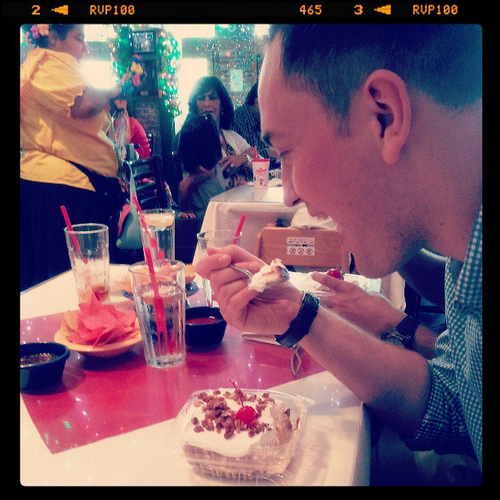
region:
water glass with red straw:
[126, 248, 200, 375]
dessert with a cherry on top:
[187, 370, 307, 482]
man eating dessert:
[218, 31, 476, 470]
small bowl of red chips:
[49, 297, 138, 365]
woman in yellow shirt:
[17, 28, 169, 255]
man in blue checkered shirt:
[246, 33, 485, 496]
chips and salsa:
[15, 286, 137, 413]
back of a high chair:
[252, 213, 344, 295]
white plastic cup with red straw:
[241, 141, 277, 203]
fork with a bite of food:
[193, 222, 320, 354]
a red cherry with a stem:
[226, 375, 258, 428]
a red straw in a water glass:
[141, 245, 169, 340]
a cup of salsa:
[177, 299, 230, 346]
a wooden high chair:
[250, 217, 352, 272]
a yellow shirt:
[17, 46, 122, 198]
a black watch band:
[264, 289, 323, 353]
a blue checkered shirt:
[404, 200, 489, 470]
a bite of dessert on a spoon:
[221, 252, 291, 298]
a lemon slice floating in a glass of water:
[141, 212, 176, 229]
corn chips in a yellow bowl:
[56, 290, 145, 367]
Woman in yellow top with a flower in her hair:
[16, 23, 123, 225]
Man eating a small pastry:
[171, 32, 466, 455]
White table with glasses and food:
[37, 241, 379, 493]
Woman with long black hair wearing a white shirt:
[189, 68, 243, 189]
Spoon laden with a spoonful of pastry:
[223, 230, 301, 299]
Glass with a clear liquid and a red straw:
[123, 253, 213, 357]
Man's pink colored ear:
[343, 58, 423, 169]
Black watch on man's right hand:
[269, 286, 341, 354]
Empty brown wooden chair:
[233, 221, 343, 272]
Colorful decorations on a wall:
[111, 38, 258, 71]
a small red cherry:
[232, 398, 259, 426]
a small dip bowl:
[20, 341, 72, 393]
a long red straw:
[141, 247, 166, 336]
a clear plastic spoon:
[218, 260, 256, 278]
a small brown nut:
[191, 425, 206, 432]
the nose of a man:
[271, 163, 303, 210]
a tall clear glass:
[129, 257, 191, 370]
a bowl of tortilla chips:
[53, 306, 145, 358]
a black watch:
[374, 305, 419, 352]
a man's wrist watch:
[275, 277, 327, 361]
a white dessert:
[165, 360, 319, 477]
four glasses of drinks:
[52, 178, 254, 366]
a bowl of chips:
[57, 280, 142, 367]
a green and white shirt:
[412, 270, 497, 442]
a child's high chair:
[257, 202, 347, 281]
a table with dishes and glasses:
[45, 215, 382, 480]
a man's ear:
[330, 62, 442, 186]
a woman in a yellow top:
[23, 43, 130, 211]